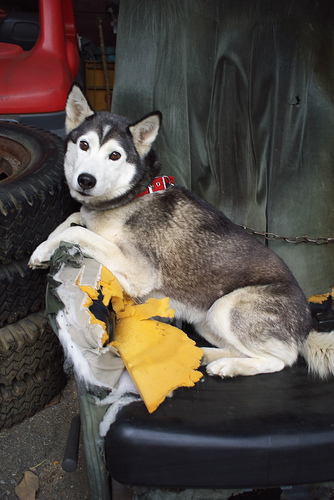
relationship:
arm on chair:
[60, 413, 84, 471] [44, 0, 332, 498]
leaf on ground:
[10, 460, 47, 498] [0, 376, 94, 498]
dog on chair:
[26, 68, 333, 382] [44, 0, 333, 499]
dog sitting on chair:
[26, 68, 333, 382] [47, 256, 332, 498]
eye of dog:
[107, 148, 123, 163] [26, 68, 333, 382]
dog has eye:
[26, 68, 333, 382] [104, 150, 124, 169]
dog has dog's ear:
[26, 68, 333, 382] [64, 81, 94, 136]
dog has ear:
[26, 68, 333, 382] [128, 107, 163, 157]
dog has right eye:
[26, 68, 333, 382] [78, 141, 87, 150]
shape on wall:
[161, 14, 327, 218] [159, 24, 332, 175]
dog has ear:
[26, 68, 333, 382] [66, 83, 90, 115]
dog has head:
[26, 68, 333, 382] [49, 70, 169, 212]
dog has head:
[26, 68, 333, 382] [63, 81, 162, 205]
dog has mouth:
[26, 68, 333, 382] [67, 172, 98, 197]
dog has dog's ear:
[26, 68, 333, 382] [128, 109, 163, 160]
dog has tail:
[26, 68, 333, 382] [300, 326, 332, 373]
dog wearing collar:
[26, 68, 333, 382] [133, 174, 173, 197]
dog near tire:
[26, 68, 333, 382] [0, 121, 81, 266]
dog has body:
[29, 68, 329, 328] [79, 178, 312, 366]